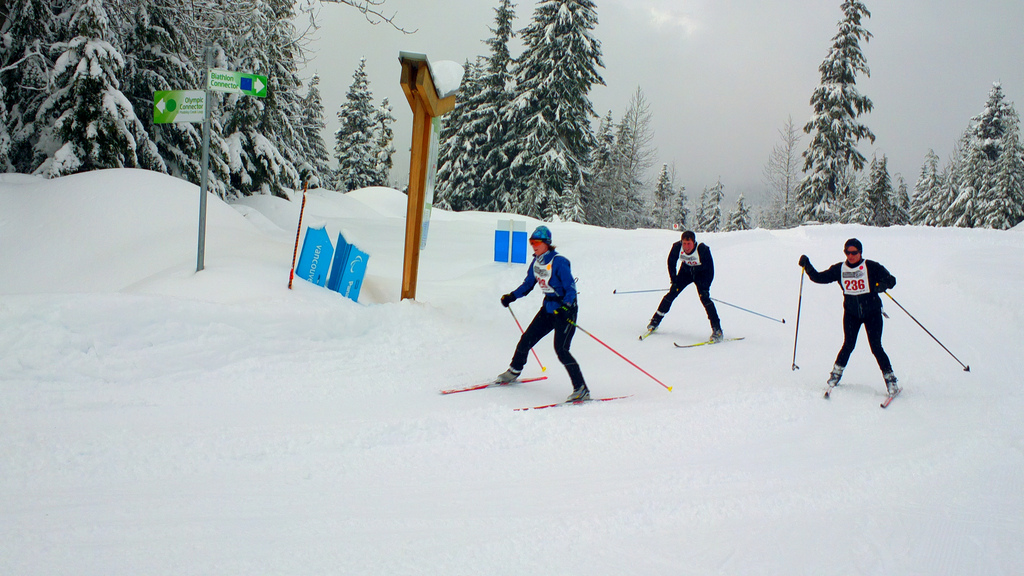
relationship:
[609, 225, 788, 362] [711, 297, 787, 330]
person holding ski pole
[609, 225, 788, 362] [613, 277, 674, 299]
person holding ski pole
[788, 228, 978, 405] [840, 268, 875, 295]
person wearing a number